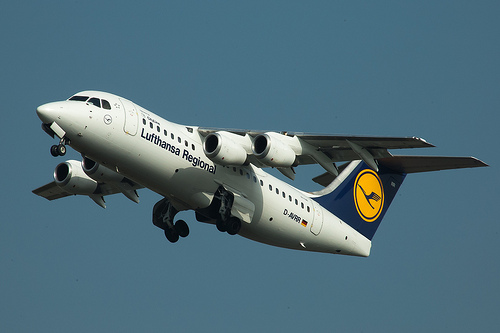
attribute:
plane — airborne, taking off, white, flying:
[30, 59, 422, 329]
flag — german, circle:
[346, 172, 401, 221]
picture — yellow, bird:
[364, 182, 375, 191]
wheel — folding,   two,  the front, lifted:
[155, 215, 206, 252]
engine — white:
[198, 119, 255, 177]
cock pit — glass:
[51, 89, 113, 142]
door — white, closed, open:
[105, 100, 154, 151]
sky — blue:
[231, 32, 300, 86]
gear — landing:
[126, 191, 234, 250]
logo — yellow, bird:
[319, 169, 396, 229]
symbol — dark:
[338, 142, 412, 218]